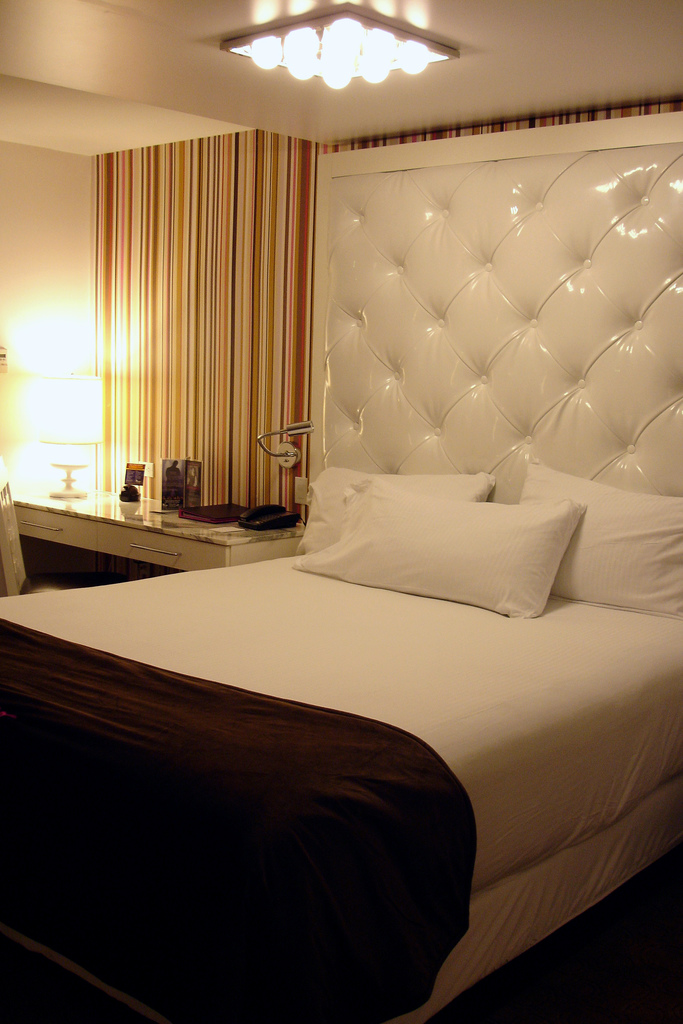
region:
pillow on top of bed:
[298, 492, 582, 616]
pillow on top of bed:
[510, 460, 680, 623]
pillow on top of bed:
[297, 458, 494, 571]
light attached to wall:
[250, 415, 319, 468]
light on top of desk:
[31, 375, 107, 497]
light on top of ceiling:
[213, 8, 469, 86]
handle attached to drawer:
[125, 534, 185, 561]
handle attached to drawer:
[20, 512, 64, 537]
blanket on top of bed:
[1, 614, 480, 1021]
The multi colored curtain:
[85, 127, 306, 513]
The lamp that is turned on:
[24, 363, 115, 504]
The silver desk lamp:
[247, 412, 322, 466]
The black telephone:
[237, 497, 301, 532]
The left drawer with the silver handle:
[14, 513, 65, 536]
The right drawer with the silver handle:
[92, 518, 200, 568]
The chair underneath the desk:
[1, 485, 62, 596]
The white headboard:
[297, 144, 681, 487]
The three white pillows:
[304, 463, 678, 631]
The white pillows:
[296, 456, 680, 629]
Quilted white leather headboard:
[322, 142, 681, 512]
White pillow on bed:
[293, 477, 586, 621]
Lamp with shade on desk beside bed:
[33, 369, 103, 497]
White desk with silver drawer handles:
[12, 488, 311, 571]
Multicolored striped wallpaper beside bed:
[90, 125, 318, 527]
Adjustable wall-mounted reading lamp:
[250, 417, 316, 470]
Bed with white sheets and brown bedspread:
[0, 553, 681, 1022]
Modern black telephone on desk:
[237, 501, 300, 531]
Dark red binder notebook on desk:
[176, 501, 254, 525]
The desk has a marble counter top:
[15, 469, 338, 581]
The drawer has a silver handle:
[70, 497, 261, 598]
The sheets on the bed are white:
[41, 518, 619, 921]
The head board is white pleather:
[286, 122, 677, 606]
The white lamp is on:
[12, 334, 184, 571]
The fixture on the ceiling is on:
[166, 10, 491, 149]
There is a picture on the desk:
[137, 422, 243, 598]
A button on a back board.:
[622, 438, 636, 454]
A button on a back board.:
[577, 375, 587, 388]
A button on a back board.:
[633, 316, 644, 332]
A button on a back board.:
[635, 194, 648, 210]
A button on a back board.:
[530, 199, 550, 216]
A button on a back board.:
[524, 314, 537, 330]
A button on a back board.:
[520, 434, 534, 439]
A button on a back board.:
[475, 367, 492, 387]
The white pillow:
[301, 533, 574, 639]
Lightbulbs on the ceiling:
[225, 11, 458, 92]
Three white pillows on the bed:
[294, 456, 680, 617]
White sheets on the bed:
[1, 494, 680, 1022]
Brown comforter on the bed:
[0, 613, 511, 1018]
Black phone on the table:
[235, 495, 297, 530]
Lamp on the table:
[33, 373, 103, 508]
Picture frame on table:
[156, 460, 208, 512]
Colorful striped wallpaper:
[90, 174, 306, 514]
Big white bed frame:
[312, 170, 681, 614]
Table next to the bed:
[12, 495, 299, 572]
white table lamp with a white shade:
[29, 373, 103, 499]